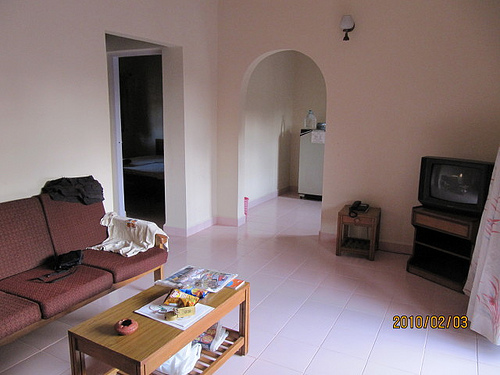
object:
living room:
[0, 0, 496, 373]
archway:
[237, 48, 328, 241]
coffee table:
[66, 264, 250, 375]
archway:
[237, 48, 329, 108]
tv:
[416, 155, 494, 219]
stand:
[405, 204, 479, 295]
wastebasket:
[243, 197, 248, 215]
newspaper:
[160, 265, 239, 293]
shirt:
[82, 211, 171, 257]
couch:
[0, 186, 168, 350]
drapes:
[462, 137, 500, 348]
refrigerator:
[298, 129, 327, 199]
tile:
[279, 279, 353, 326]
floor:
[0, 193, 500, 375]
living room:
[0, 0, 500, 375]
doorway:
[232, 49, 328, 241]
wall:
[0, 0, 214, 233]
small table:
[335, 205, 381, 261]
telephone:
[348, 199, 369, 218]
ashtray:
[114, 318, 139, 335]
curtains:
[462, 141, 500, 352]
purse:
[28, 249, 84, 284]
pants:
[41, 174, 106, 206]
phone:
[349, 200, 370, 218]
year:
[391, 314, 424, 331]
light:
[338, 13, 355, 42]